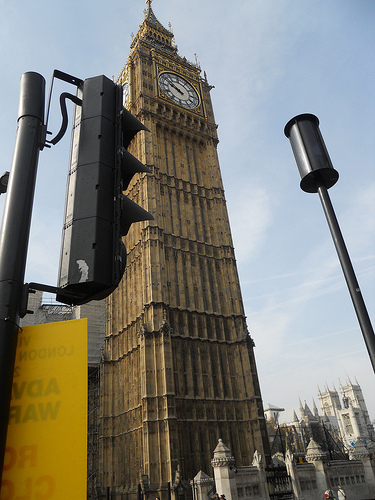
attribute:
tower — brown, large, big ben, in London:
[96, 2, 269, 499]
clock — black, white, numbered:
[155, 67, 204, 109]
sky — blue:
[2, 1, 374, 402]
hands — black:
[165, 75, 185, 97]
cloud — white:
[234, 199, 266, 251]